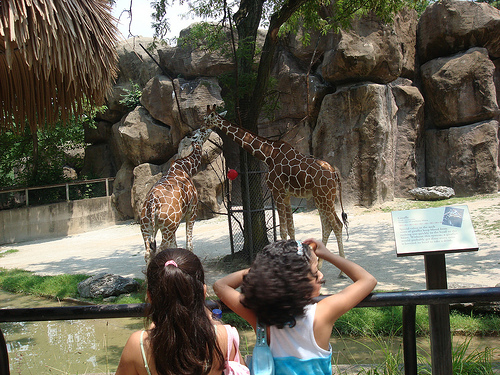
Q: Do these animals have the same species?
A: Yes, all the animals are giraffes.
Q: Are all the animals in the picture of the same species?
A: Yes, all the animals are giraffes.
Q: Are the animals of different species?
A: No, all the animals are giraffes.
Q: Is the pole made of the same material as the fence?
A: Yes, both the pole and the fence are made of metal.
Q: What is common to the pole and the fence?
A: The material, both the pole and the fence are metallic.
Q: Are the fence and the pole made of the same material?
A: Yes, both the fence and the pole are made of metal.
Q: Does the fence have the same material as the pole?
A: Yes, both the fence and the pole are made of metal.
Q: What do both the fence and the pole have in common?
A: The material, both the fence and the pole are metallic.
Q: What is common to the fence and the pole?
A: The material, both the fence and the pole are metallic.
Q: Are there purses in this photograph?
A: Yes, there is a purse.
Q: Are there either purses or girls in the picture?
A: Yes, there is a purse.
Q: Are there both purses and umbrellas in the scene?
A: No, there is a purse but no umbrellas.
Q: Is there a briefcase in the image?
A: No, there are no briefcases.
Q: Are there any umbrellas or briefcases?
A: No, there are no briefcases or umbrellas.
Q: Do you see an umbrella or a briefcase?
A: No, there are no briefcases or umbrellas.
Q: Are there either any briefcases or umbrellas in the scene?
A: No, there are no briefcases or umbrellas.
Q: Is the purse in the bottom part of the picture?
A: Yes, the purse is in the bottom of the image.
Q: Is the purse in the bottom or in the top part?
A: The purse is in the bottom of the image.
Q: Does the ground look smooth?
A: Yes, the ground is smooth.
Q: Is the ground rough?
A: No, the ground is smooth.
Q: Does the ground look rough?
A: No, the ground is smooth.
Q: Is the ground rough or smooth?
A: The ground is smooth.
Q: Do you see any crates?
A: No, there are no crates.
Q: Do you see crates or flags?
A: No, there are no crates or flags.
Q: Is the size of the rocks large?
A: Yes, the rocks are large.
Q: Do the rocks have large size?
A: Yes, the rocks are large.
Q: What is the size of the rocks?
A: The rocks are large.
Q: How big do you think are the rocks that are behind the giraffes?
A: The rocks are large.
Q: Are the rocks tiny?
A: No, the rocks are large.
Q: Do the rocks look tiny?
A: No, the rocks are large.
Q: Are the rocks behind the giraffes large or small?
A: The rocks are large.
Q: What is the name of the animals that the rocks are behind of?
A: The animals are giraffes.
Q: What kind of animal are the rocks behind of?
A: The rocks are behind the giraffes.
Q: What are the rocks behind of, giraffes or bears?
A: The rocks are behind giraffes.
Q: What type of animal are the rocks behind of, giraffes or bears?
A: The rocks are behind giraffes.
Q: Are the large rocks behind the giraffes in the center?
A: Yes, the rocks are behind the giraffes.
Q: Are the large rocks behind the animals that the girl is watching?
A: Yes, the rocks are behind the giraffes.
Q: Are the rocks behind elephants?
A: No, the rocks are behind the giraffes.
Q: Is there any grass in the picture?
A: Yes, there is grass.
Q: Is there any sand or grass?
A: Yes, there is grass.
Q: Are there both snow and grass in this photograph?
A: No, there is grass but no snow.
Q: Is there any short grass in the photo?
A: Yes, there is short grass.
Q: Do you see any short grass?
A: Yes, there is short grass.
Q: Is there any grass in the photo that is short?
A: Yes, there is grass that is short.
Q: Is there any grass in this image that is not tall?
A: Yes, there is short grass.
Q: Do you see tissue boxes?
A: No, there are no tissue boxes.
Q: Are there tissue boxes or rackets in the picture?
A: No, there are no tissue boxes or rackets.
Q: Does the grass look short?
A: Yes, the grass is short.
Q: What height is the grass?
A: The grass is short.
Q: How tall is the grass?
A: The grass is short.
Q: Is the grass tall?
A: No, the grass is short.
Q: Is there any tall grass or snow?
A: No, there is grass but it is short.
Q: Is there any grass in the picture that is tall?
A: No, there is grass but it is short.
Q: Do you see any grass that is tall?
A: No, there is grass but it is short.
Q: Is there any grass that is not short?
A: No, there is grass but it is short.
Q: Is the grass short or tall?
A: The grass is short.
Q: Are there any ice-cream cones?
A: No, there are no ice-cream cones.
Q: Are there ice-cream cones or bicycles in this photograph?
A: No, there are no ice-cream cones or bicycles.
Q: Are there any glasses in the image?
A: No, there are no glasses.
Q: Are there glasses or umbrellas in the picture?
A: No, there are no glasses or umbrellas.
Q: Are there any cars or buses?
A: No, there are no cars or buses.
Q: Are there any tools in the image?
A: No, there are no tools.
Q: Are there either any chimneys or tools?
A: No, there are no tools or chimneys.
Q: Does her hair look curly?
A: Yes, the hair is curly.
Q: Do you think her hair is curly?
A: Yes, the hair is curly.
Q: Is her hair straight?
A: No, the hair is curly.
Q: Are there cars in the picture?
A: No, there are no cars.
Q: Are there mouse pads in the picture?
A: No, there are no mouse pads.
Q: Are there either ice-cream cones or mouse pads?
A: No, there are no mouse pads or ice-cream cones.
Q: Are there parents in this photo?
A: No, there are no parents.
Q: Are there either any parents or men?
A: No, there are no parents or men.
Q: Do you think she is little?
A: Yes, the girl is little.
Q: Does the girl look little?
A: Yes, the girl is little.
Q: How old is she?
A: The girl is little.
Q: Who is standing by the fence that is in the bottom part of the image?
A: The girl is standing by the fence.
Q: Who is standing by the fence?
A: The girl is standing by the fence.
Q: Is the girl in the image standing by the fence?
A: Yes, the girl is standing by the fence.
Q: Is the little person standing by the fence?
A: Yes, the girl is standing by the fence.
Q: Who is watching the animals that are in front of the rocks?
A: The girl is watching the giraffes.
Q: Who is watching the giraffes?
A: The girl is watching the giraffes.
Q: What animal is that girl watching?
A: The girl is watching the giraffes.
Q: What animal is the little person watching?
A: The girl is watching the giraffes.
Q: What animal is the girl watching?
A: The girl is watching the giraffes.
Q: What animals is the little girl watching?
A: The girl is watching the giraffes.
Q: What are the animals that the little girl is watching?
A: The animals are giraffes.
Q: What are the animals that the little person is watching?
A: The animals are giraffes.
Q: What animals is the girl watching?
A: The girl is watching the giraffes.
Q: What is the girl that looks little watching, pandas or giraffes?
A: The girl is watching giraffes.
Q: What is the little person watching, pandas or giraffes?
A: The girl is watching giraffes.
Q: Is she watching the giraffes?
A: Yes, the girl is watching the giraffes.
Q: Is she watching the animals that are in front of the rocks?
A: Yes, the girl is watching the giraffes.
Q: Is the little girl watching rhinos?
A: No, the girl is watching the giraffes.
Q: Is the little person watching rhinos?
A: No, the girl is watching the giraffes.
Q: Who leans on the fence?
A: The girl leans on the fence.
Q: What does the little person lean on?
A: The girl leans on the fence.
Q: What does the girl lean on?
A: The girl leans on the fence.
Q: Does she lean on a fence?
A: Yes, the girl leans on a fence.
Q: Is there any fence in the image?
A: Yes, there is a fence.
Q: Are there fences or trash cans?
A: Yes, there is a fence.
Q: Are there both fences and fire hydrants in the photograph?
A: No, there is a fence but no fire hydrants.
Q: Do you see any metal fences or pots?
A: Yes, there is a metal fence.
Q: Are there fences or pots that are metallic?
A: Yes, the fence is metallic.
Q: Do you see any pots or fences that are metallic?
A: Yes, the fence is metallic.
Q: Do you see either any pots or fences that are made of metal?
A: Yes, the fence is made of metal.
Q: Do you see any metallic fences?
A: Yes, there is a metal fence.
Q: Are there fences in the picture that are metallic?
A: Yes, there is a fence that is metallic.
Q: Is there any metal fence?
A: Yes, there is a fence that is made of metal.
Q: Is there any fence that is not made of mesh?
A: Yes, there is a fence that is made of metal.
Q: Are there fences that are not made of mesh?
A: Yes, there is a fence that is made of metal.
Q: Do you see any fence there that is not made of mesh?
A: Yes, there is a fence that is made of metal.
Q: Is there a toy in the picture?
A: No, there are no toys.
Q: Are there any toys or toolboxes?
A: No, there are no toys or toolboxes.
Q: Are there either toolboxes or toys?
A: No, there are no toys or toolboxes.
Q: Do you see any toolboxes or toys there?
A: No, there are no toys or toolboxes.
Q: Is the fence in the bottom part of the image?
A: Yes, the fence is in the bottom of the image.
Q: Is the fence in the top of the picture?
A: No, the fence is in the bottom of the image.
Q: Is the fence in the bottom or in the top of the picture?
A: The fence is in the bottom of the image.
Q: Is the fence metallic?
A: Yes, the fence is metallic.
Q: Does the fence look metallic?
A: Yes, the fence is metallic.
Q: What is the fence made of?
A: The fence is made of metal.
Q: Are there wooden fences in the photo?
A: No, there is a fence but it is metallic.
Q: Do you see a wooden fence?
A: No, there is a fence but it is metallic.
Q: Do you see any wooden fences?
A: No, there is a fence but it is metallic.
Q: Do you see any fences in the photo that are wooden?
A: No, there is a fence but it is metallic.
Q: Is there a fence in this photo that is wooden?
A: No, there is a fence but it is metallic.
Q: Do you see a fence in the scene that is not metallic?
A: No, there is a fence but it is metallic.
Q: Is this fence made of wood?
A: No, the fence is made of metal.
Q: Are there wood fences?
A: No, there is a fence but it is made of metal.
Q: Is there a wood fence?
A: No, there is a fence but it is made of metal.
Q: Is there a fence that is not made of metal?
A: No, there is a fence but it is made of metal.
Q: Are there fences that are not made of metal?
A: No, there is a fence but it is made of metal.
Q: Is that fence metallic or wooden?
A: The fence is metallic.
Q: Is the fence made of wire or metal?
A: The fence is made of metal.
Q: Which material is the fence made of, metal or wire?
A: The fence is made of metal.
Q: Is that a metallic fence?
A: Yes, that is a metallic fence.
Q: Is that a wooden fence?
A: No, that is a metallic fence.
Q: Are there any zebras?
A: No, there are no zebras.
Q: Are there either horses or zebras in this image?
A: No, there are no zebras or horses.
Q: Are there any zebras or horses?
A: No, there are no zebras or horses.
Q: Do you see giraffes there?
A: Yes, there are giraffes.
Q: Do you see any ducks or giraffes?
A: Yes, there are giraffes.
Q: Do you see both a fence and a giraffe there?
A: Yes, there are both a giraffe and a fence.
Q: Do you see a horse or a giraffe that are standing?
A: Yes, the giraffes are standing.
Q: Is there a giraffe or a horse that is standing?
A: Yes, the giraffes are standing.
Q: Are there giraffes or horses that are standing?
A: Yes, the giraffes are standing.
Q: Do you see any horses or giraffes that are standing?
A: Yes, the giraffes are standing.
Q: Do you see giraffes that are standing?
A: Yes, there are giraffes that are standing.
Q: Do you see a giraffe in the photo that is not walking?
A: Yes, there are giraffes that are standing .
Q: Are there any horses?
A: No, there are no horses.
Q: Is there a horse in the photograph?
A: No, there are no horses.